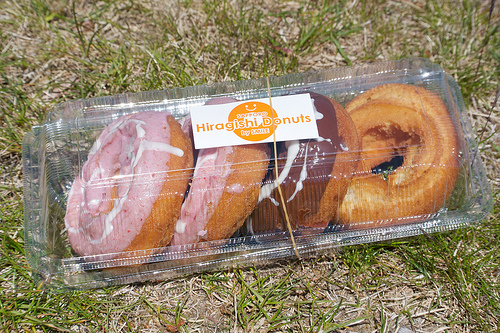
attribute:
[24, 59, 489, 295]
container — plastic, clear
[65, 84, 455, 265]
donuts — cooked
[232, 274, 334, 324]
grass — green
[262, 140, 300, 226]
band — rubber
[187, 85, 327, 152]
tag — white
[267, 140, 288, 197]
band — rubber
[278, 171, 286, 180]
frosting — white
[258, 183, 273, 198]
frosting — white, chocolate frosted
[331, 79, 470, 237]
donut — plain, brown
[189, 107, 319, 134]
letters — orange, company name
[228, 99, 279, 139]
circle — orange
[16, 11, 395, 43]
ground — grass, dirt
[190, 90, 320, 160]
label — white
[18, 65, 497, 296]
case — plastic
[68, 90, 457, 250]
donuts — frosted pink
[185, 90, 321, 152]
sticker — white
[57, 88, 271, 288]
donuts — white, iced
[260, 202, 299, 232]
frosting — chocolate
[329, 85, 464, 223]
donut — plain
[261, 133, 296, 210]
band — rubber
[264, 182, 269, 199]
frosting — white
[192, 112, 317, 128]
writing — orange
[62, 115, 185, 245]
frosting — white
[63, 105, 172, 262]
icing — pink